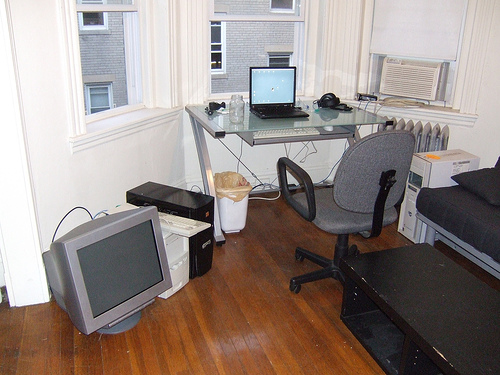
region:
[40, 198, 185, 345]
Computer monitor sitting on the floor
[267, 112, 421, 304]
Grey office chair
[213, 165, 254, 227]
White garbage can with grocery bag inside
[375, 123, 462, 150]
Grey radiator attached to the wall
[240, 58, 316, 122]
Laptop sitting on computer desk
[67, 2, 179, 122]
Window with view of brick building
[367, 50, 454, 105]
White air conditioner in window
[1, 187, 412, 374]
Wooden floor covered in dust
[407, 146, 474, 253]
White computer tower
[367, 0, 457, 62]
Window blinds pulled closed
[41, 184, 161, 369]
This is a large monitor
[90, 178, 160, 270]
this is a computer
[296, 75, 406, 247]
this is a chair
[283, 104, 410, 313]
this is an office chair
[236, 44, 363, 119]
this is a laptop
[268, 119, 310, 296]
this is a handle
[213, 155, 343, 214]
the handle is black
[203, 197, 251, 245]
this is a trashcan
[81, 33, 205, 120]
this is a window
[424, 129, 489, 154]
this is a vent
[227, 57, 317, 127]
a black laptop computer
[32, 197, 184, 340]
an old computer monitor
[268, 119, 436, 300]
a black and grey office chair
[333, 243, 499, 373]
a black coffee table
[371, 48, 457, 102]
a small air conditioning unit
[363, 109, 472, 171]
a grey space heater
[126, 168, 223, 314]
old and unplugged computers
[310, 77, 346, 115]
a pair of black headphones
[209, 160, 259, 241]
a white garbage can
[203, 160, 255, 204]
a brown plastic bag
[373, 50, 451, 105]
this apartment has a window air conditioner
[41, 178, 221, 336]
desktop computer elements on the floor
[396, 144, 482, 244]
computer tower on the other side of the desk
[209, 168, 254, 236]
trash can lined with a plastic grocery bag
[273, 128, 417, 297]
the desk chair has five casters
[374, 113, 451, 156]
radiator under the window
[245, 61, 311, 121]
laptop computer on the desk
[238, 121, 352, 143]
a drawer under the desk holds a keyboard and mouse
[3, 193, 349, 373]
the floor is laid with wood paneling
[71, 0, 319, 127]
the windows have a view of the building across the way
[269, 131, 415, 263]
A chair behind the desk.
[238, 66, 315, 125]
A laptop on the table.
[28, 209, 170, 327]
A television on the floor.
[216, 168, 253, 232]
White garbage can under the desk.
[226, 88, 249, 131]
A empty jar on the desk.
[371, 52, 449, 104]
Air conditioner unit in the window.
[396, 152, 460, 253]
The tower to a computer on the floor.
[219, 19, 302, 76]
The window is open.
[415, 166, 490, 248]
a black sofa next to box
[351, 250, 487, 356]
A table in front of the sofa.